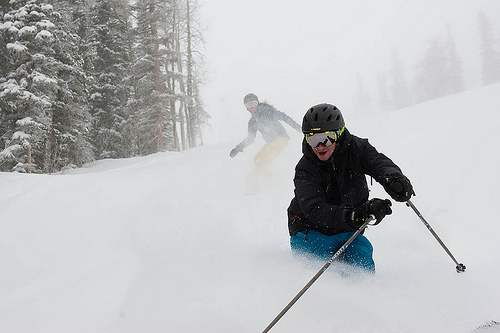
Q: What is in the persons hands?
A: Ski poles.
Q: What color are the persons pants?
A: Blue.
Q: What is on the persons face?
A: Goggles.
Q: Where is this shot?
A: Mountain.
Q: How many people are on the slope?
A: 2.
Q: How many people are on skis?
A: 1.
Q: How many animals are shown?
A: 0.